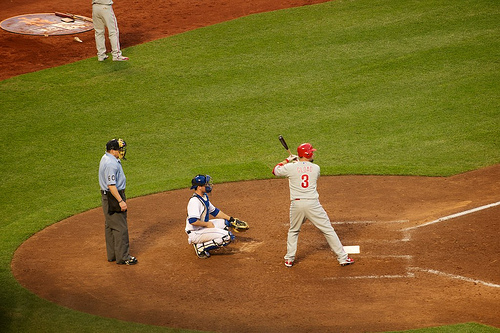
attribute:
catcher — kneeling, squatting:
[179, 170, 252, 262]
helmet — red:
[296, 141, 319, 157]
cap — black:
[103, 136, 126, 150]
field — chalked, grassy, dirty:
[0, 0, 499, 332]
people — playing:
[78, 1, 361, 270]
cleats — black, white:
[107, 253, 143, 268]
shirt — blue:
[96, 150, 131, 191]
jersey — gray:
[278, 157, 326, 198]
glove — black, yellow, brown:
[230, 212, 251, 236]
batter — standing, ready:
[272, 130, 361, 271]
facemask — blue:
[202, 172, 215, 197]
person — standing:
[85, 0, 134, 66]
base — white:
[333, 239, 364, 256]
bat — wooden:
[275, 132, 301, 162]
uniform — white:
[180, 194, 236, 249]